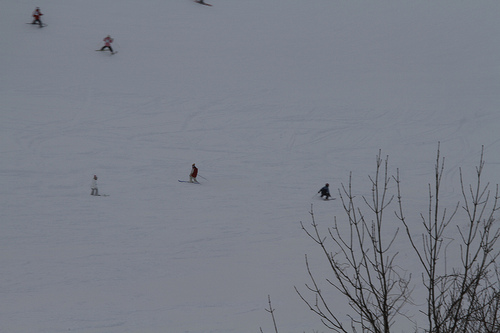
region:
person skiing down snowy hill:
[19, 6, 50, 31]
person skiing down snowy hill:
[90, 31, 120, 54]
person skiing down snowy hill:
[79, 169, 114, 203]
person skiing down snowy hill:
[186, 156, 211, 194]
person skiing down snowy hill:
[323, 180, 339, 202]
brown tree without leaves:
[343, 149, 494, 317]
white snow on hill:
[11, 44, 81, 164]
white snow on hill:
[151, 16, 456, 133]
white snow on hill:
[14, 210, 274, 292]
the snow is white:
[167, 277, 200, 326]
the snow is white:
[116, 225, 167, 285]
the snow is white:
[208, 251, 250, 322]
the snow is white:
[201, 278, 233, 324]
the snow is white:
[224, 298, 242, 329]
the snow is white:
[176, 251, 216, 310]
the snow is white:
[188, 271, 238, 331]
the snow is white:
[195, 261, 223, 293]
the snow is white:
[225, 307, 238, 322]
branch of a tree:
[434, 232, 445, 250]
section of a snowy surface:
[145, 285, 160, 288]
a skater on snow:
[91, 178, 97, 188]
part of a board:
[183, 179, 198, 182]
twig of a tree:
[368, 288, 383, 298]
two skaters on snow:
[29, 20, 113, 27]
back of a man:
[324, 183, 326, 191]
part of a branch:
[372, 287, 381, 301]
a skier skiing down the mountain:
[90, 172, 107, 196]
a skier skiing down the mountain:
[182, 160, 203, 188]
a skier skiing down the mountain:
[316, 181, 331, 199]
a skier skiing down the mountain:
[94, 33, 119, 56]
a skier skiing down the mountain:
[28, 8, 45, 28]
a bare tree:
[243, 144, 498, 331]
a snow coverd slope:
[2, 3, 495, 331]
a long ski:
[175, 177, 198, 185]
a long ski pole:
[197, 170, 207, 181]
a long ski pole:
[307, 190, 319, 200]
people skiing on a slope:
[69, 126, 377, 231]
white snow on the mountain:
[231, 39, 439, 126]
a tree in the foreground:
[225, 131, 498, 306]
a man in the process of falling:
[79, 19, 130, 62]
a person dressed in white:
[69, 168, 119, 205]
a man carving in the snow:
[290, 159, 347, 206]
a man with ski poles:
[143, 133, 228, 195]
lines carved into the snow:
[214, 99, 306, 161]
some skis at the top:
[182, 0, 251, 31]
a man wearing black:
[288, 160, 361, 211]